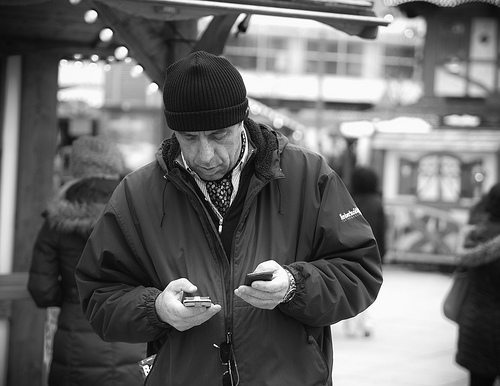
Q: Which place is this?
A: It is a city.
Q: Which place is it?
A: It is a city.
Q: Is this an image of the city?
A: Yes, it is showing the city.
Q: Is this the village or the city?
A: It is the city.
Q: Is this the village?
A: No, it is the city.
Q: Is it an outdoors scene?
A: Yes, it is outdoors.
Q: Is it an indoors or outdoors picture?
A: It is outdoors.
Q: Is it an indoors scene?
A: No, it is outdoors.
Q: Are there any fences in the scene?
A: No, there are no fences.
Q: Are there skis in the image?
A: No, there are no skis.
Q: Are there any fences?
A: No, there are no fences.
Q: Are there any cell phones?
A: Yes, there are cell phones.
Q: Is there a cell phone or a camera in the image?
A: Yes, there are cell phones.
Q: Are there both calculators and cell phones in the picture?
A: No, there are cell phones but no calculators.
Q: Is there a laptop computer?
A: No, there are no laptops.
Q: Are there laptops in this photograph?
A: No, there are no laptops.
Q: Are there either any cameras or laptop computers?
A: No, there are no laptop computers or cameras.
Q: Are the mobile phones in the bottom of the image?
A: Yes, the mobile phones are in the bottom of the image.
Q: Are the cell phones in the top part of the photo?
A: No, the cell phones are in the bottom of the image.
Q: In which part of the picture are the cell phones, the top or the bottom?
A: The cell phones are in the bottom of the image.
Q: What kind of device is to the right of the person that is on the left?
A: The devices are cell phones.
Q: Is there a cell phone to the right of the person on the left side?
A: Yes, there are cell phones to the right of the person.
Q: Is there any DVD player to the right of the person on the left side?
A: No, there are cell phones to the right of the person.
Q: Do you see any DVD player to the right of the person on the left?
A: No, there are cell phones to the right of the person.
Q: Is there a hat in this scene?
A: Yes, there is a hat.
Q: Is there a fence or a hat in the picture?
A: Yes, there is a hat.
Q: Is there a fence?
A: No, there are no fences.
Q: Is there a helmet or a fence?
A: No, there are no fences or helmets.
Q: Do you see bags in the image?
A: Yes, there is a bag.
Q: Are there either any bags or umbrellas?
A: Yes, there is a bag.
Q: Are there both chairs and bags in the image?
A: No, there is a bag but no chairs.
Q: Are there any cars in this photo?
A: No, there are no cars.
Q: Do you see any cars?
A: No, there are no cars.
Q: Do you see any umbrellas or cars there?
A: No, there are no cars or umbrellas.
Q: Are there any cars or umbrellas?
A: No, there are no cars or umbrellas.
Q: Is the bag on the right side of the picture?
A: Yes, the bag is on the right of the image.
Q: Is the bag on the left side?
A: No, the bag is on the right of the image.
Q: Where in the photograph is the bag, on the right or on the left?
A: The bag is on the right of the image.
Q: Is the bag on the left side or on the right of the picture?
A: The bag is on the right of the image.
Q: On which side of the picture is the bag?
A: The bag is on the right of the image.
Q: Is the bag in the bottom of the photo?
A: Yes, the bag is in the bottom of the image.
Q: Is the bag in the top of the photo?
A: No, the bag is in the bottom of the image.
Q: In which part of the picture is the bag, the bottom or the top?
A: The bag is in the bottom of the image.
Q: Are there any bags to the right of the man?
A: Yes, there is a bag to the right of the man.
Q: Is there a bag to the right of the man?
A: Yes, there is a bag to the right of the man.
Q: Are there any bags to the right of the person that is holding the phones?
A: Yes, there is a bag to the right of the man.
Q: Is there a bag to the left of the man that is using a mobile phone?
A: No, the bag is to the right of the man.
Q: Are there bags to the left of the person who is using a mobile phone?
A: No, the bag is to the right of the man.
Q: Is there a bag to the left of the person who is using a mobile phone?
A: No, the bag is to the right of the man.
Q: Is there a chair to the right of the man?
A: No, there is a bag to the right of the man.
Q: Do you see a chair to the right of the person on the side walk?
A: No, there is a bag to the right of the man.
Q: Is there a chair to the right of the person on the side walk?
A: No, there is a bag to the right of the man.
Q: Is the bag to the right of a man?
A: Yes, the bag is to the right of a man.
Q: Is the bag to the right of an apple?
A: No, the bag is to the right of a man.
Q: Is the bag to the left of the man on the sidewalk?
A: No, the bag is to the right of the man.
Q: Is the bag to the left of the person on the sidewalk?
A: No, the bag is to the right of the man.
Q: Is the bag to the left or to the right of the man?
A: The bag is to the right of the man.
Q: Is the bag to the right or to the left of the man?
A: The bag is to the right of the man.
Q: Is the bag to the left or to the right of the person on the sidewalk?
A: The bag is to the right of the man.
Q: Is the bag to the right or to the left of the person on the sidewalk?
A: The bag is to the right of the man.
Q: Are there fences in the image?
A: No, there are no fences.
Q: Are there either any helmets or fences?
A: No, there are no fences or helmets.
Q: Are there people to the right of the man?
A: Yes, there is a person to the right of the man.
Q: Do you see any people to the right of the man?
A: Yes, there is a person to the right of the man.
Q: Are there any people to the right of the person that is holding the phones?
A: Yes, there is a person to the right of the man.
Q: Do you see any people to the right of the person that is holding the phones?
A: Yes, there is a person to the right of the man.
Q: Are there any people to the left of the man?
A: No, the person is to the right of the man.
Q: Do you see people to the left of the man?
A: No, the person is to the right of the man.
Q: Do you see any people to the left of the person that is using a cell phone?
A: No, the person is to the right of the man.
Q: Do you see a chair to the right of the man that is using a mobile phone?
A: No, there is a person to the right of the man.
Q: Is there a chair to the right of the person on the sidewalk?
A: No, there is a person to the right of the man.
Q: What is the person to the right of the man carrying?
A: The person is carrying a bag.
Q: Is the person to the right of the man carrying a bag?
A: Yes, the person is carrying a bag.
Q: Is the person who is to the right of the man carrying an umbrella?
A: No, the person is carrying a bag.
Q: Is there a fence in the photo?
A: No, there are no fences.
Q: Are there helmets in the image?
A: No, there are no helmets.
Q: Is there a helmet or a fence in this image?
A: No, there are no helmets or fences.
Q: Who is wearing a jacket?
A: The man is wearing a jacket.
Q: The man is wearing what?
A: The man is wearing a jacket.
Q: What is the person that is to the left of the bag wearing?
A: The man is wearing a jacket.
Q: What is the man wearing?
A: The man is wearing a jacket.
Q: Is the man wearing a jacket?
A: Yes, the man is wearing a jacket.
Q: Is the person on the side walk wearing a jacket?
A: Yes, the man is wearing a jacket.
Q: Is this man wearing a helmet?
A: No, the man is wearing a jacket.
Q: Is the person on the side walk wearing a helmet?
A: No, the man is wearing a jacket.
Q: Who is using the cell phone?
A: The man is using the cell phone.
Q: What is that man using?
A: The man is using a cell phone.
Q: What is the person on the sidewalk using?
A: The man is using a cell phone.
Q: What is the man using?
A: The man is using a cell phone.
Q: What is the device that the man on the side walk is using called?
A: The device is a cell phone.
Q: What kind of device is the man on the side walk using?
A: The man is using a mobile phone.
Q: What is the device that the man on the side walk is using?
A: The device is a cell phone.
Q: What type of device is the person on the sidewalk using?
A: The man is using a mobile phone.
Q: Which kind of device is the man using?
A: The man is using a mobile phone.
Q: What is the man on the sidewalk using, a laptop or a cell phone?
A: The man is using a cell phone.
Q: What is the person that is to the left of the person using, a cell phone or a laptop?
A: The man is using a cell phone.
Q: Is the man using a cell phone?
A: Yes, the man is using a cell phone.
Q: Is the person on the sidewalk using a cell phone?
A: Yes, the man is using a cell phone.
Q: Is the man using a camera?
A: No, the man is using a cell phone.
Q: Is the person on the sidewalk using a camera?
A: No, the man is using a cell phone.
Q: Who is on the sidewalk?
A: The man is on the sidewalk.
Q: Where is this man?
A: The man is on the sidewalk.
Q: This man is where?
A: The man is on the sidewalk.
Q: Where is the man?
A: The man is on the sidewalk.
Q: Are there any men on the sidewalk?
A: Yes, there is a man on the sidewalk.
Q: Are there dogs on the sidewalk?
A: No, there is a man on the sidewalk.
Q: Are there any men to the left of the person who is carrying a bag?
A: Yes, there is a man to the left of the person.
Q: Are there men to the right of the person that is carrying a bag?
A: No, the man is to the left of the person.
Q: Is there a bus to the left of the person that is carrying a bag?
A: No, there is a man to the left of the person.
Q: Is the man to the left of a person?
A: Yes, the man is to the left of a person.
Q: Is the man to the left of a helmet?
A: No, the man is to the left of a person.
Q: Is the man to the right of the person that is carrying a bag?
A: No, the man is to the left of the person.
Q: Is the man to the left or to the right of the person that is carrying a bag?
A: The man is to the left of the person.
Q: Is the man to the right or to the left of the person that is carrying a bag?
A: The man is to the left of the person.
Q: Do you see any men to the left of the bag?
A: Yes, there is a man to the left of the bag.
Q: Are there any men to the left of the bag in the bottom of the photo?
A: Yes, there is a man to the left of the bag.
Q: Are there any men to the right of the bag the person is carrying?
A: No, the man is to the left of the bag.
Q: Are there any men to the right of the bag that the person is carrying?
A: No, the man is to the left of the bag.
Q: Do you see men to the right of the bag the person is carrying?
A: No, the man is to the left of the bag.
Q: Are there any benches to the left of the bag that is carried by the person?
A: No, there is a man to the left of the bag.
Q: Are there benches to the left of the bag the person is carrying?
A: No, there is a man to the left of the bag.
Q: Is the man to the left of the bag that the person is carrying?
A: Yes, the man is to the left of the bag.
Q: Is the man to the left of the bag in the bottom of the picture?
A: Yes, the man is to the left of the bag.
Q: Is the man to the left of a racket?
A: No, the man is to the left of the bag.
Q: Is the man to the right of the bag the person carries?
A: No, the man is to the left of the bag.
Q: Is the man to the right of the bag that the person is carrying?
A: No, the man is to the left of the bag.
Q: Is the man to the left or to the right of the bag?
A: The man is to the left of the bag.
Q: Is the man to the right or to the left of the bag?
A: The man is to the left of the bag.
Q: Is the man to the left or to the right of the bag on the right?
A: The man is to the left of the bag.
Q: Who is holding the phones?
A: The man is holding the phones.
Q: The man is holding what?
A: The man is holding the phones.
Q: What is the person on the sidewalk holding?
A: The man is holding the phones.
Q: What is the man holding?
A: The man is holding the phones.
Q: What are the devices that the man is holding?
A: The devices are phones.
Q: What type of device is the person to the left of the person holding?
A: The man is holding the phones.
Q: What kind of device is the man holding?
A: The man is holding the phones.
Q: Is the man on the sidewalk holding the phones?
A: Yes, the man is holding the phones.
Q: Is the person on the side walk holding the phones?
A: Yes, the man is holding the phones.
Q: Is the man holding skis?
A: No, the man is holding the phones.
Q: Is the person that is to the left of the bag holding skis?
A: No, the man is holding the phones.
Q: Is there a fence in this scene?
A: No, there are no fences.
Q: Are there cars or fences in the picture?
A: No, there are no fences or cars.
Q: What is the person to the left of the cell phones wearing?
A: The person is wearing a jacket.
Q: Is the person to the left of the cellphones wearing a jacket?
A: Yes, the person is wearing a jacket.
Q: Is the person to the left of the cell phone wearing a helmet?
A: No, the person is wearing a jacket.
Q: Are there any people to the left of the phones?
A: Yes, there is a person to the left of the phones.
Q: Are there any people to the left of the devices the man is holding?
A: Yes, there is a person to the left of the phones.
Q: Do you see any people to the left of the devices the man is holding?
A: Yes, there is a person to the left of the phones.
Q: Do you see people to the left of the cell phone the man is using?
A: Yes, there is a person to the left of the cellphone.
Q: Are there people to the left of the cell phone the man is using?
A: Yes, there is a person to the left of the cellphone.